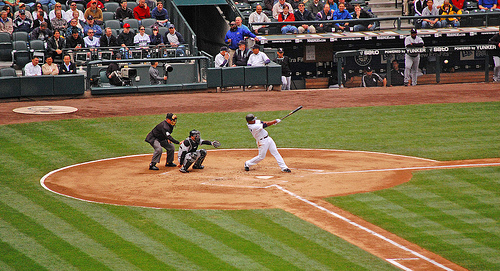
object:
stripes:
[4, 213, 238, 268]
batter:
[244, 114, 291, 173]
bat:
[280, 106, 303, 121]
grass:
[7, 201, 331, 263]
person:
[401, 28, 426, 86]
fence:
[0, 56, 332, 101]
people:
[236, 17, 251, 40]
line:
[388, 166, 435, 171]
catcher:
[177, 129, 221, 173]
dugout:
[259, 25, 499, 89]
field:
[0, 87, 498, 269]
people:
[24, 57, 41, 76]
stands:
[0, 1, 498, 88]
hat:
[123, 23, 131, 28]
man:
[117, 23, 135, 54]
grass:
[424, 182, 499, 245]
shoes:
[244, 162, 293, 173]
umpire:
[145, 113, 184, 171]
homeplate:
[255, 174, 274, 179]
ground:
[2, 84, 497, 269]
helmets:
[246, 114, 258, 121]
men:
[224, 21, 259, 67]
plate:
[12, 106, 78, 115]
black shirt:
[145, 120, 180, 144]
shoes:
[149, 162, 177, 170]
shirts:
[246, 120, 268, 140]